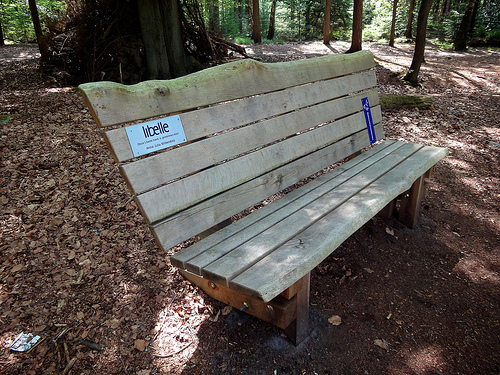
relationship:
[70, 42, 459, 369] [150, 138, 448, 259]
bench has slat